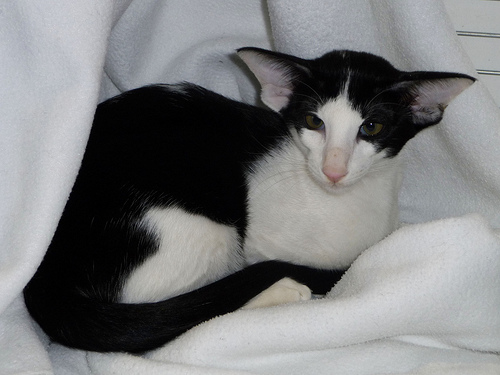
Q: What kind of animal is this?
A: Cat.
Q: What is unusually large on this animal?
A: The ears.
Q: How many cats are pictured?
A: One.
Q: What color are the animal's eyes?
A: Green.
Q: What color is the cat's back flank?
A: Black.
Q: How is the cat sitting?
A: Curled up.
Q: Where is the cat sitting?
A: On a blanket.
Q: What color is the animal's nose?
A: Pink.